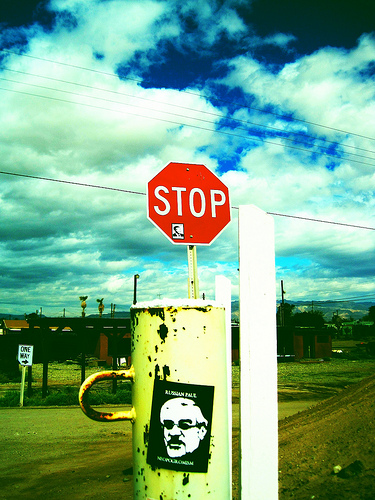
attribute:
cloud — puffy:
[232, 44, 373, 171]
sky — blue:
[1, 3, 373, 303]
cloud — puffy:
[36, 0, 258, 66]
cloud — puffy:
[6, 46, 224, 173]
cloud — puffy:
[211, 140, 374, 258]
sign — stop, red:
[149, 161, 231, 245]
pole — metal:
[186, 247, 198, 298]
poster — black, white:
[145, 379, 215, 474]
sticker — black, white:
[170, 223, 184, 241]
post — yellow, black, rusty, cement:
[127, 302, 235, 497]